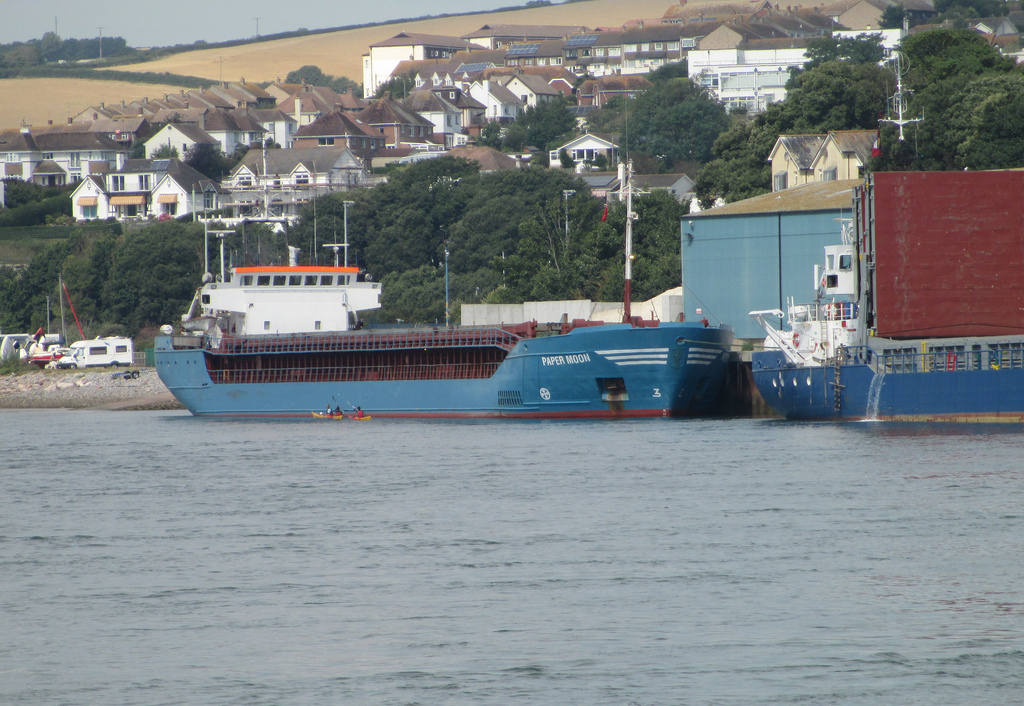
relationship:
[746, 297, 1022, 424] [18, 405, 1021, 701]
boat in water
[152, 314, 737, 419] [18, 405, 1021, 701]
boat in water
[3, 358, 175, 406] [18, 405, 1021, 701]
rocks next to water